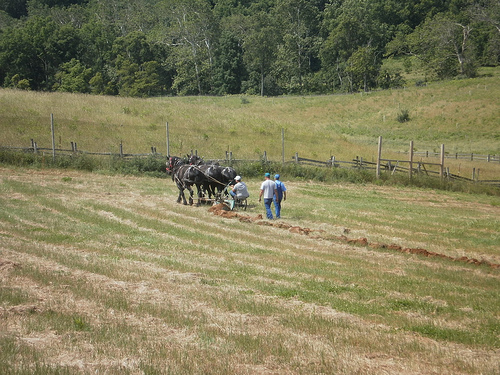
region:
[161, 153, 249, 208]
a man riding behind horses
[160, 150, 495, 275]
men and horses working to till a field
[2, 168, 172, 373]
a freshly mowed field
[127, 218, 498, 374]
a filed with dirt torn up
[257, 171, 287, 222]
two men walking in a field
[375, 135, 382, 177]
a wooden post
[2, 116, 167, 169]
a section of a fence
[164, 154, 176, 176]
a horse's head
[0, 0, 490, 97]
trees and brush in the distance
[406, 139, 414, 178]
a wooden fence post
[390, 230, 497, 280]
furrow in the ground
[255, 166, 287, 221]
two men walking side by side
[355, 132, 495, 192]
wooden fences along property lines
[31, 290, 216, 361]
brown grass in a field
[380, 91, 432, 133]
solitary green bush on a hillside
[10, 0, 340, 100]
a long tree line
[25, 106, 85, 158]
tall pole between shorter ones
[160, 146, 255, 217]
horses pulling a man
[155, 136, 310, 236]
farmhands furrow the earth ahead of planting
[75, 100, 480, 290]
spring activity on a farm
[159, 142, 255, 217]
horses pulling a carriage in the grass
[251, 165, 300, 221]
two men walking along the grass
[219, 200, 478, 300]
line of dirt in the grass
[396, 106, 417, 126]
small shrub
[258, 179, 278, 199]
bright white tee shirt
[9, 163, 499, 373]
field of green and brown grass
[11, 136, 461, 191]
small wooden fence along the edge of the enclosure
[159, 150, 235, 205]
two dark horses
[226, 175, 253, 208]
person crouched down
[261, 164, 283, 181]
two blue hats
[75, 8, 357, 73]
The trees are green.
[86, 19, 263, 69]
Trees are in the background.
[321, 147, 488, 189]
The fence is gray.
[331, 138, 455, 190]
The fence is made of wood.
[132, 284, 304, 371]
Stripes are in the grass.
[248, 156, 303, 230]
People are walking.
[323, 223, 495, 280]
The dirt is brown.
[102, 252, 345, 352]
The grass is green.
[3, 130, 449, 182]
The field has a fence around it.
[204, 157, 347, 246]
People are in the field.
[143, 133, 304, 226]
people working in a farm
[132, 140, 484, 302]
people preparing the field to grow food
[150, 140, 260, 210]
two horses pulling a small cart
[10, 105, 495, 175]
the field has fences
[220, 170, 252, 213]
a man sitting in a small cart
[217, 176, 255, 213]
man sitting on a cart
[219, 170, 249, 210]
man wears a white hat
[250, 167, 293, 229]
two people walking behind the horses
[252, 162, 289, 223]
men wearing blue caps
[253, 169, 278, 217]
man wearing white short